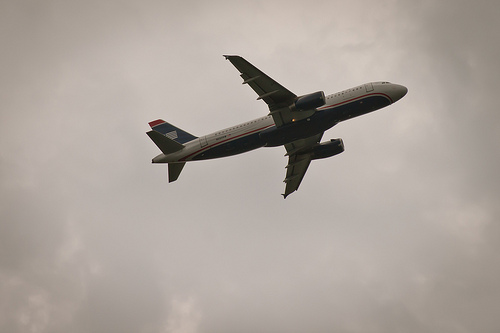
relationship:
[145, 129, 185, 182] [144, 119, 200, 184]
small wings under tail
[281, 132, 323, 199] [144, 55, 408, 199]
wing of airplane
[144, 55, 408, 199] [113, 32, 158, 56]
airplane against gray overcast sky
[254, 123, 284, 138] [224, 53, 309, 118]
cylinder under both wing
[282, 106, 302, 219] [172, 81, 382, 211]
light under plane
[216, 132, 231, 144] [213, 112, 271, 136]
writing under windows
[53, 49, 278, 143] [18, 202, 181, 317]
overcast clouds in sky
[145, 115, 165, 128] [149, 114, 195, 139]
tip on tail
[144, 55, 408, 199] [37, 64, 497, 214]
airplane in air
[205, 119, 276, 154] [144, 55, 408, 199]
red stripe on airplane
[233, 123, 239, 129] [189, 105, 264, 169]
window for passengers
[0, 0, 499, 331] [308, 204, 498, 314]
sky has cloud cover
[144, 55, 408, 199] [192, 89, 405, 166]
airplane has bottom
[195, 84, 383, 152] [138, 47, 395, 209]
line on plane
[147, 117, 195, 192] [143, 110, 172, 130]
tail has tip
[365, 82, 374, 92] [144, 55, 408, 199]
door on side of airplane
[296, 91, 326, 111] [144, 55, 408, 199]
engine on airplane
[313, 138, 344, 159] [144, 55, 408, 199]
engine on airplane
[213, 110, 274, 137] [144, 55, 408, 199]
windows are on airplane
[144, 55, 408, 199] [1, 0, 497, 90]
airplane in sky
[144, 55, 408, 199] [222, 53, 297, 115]
airplane has wing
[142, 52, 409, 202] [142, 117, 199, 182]
airplane has tail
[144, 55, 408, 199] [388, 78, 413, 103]
airplane has nose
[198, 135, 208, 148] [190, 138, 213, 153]
back door has back door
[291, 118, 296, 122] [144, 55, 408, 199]
light on airplane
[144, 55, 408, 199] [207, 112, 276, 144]
airplane has windows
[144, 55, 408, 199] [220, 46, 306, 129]
airplane has wing